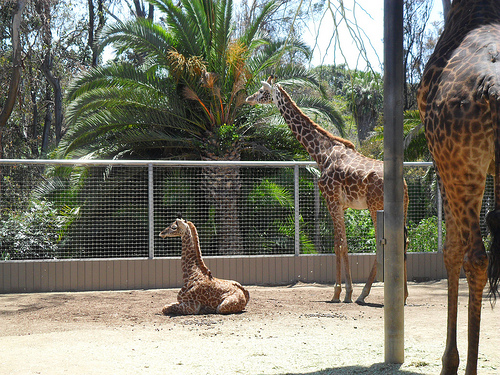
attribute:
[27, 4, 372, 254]
tree — large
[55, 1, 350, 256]
palm tree — beside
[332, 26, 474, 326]
pole — metal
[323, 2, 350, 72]
vine — small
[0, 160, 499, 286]
fence — silver, secured 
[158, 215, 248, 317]
small giraffe — sitting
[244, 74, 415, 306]
giraffe — tall, brown, beige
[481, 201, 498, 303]
tail — black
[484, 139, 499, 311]
tail — black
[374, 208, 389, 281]
box — metal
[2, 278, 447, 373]
ground — dirt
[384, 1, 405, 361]
pole — silver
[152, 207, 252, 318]
giraffe — small, brown, beige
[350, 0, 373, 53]
sky — blue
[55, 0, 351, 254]
tree — palm tree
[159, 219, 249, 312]
giraffe — small